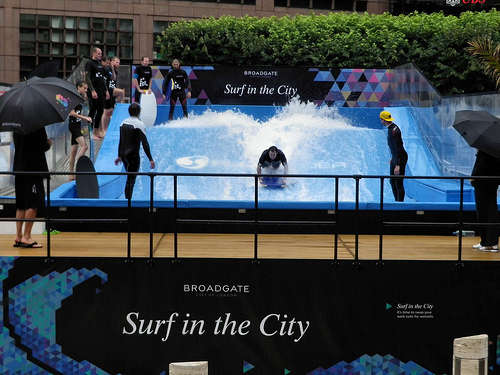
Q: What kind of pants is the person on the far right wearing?
A: Shorts.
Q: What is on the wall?
A: A sign.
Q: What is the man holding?
A: An umbrella.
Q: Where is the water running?
A: Down a ramp.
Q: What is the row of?
A: Bushes.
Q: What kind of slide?
A: Water slide.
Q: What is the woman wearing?
A: Sandals.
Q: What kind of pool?
A: Wave pool.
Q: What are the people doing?
A: Surfing.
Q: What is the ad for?
A: Pool.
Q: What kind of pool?
A: Surf.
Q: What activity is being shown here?
A: Surfing.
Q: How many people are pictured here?
A: Eleven.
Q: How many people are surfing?
A: One.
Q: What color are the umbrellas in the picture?
A: Black.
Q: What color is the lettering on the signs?
A: White.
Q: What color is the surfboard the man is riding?
A: Blue.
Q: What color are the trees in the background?
A: Green.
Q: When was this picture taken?
A: Daytime.